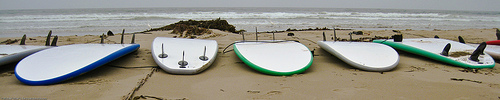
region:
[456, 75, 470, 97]
black mark is spotted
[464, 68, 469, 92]
black mark is spotted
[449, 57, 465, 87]
black mark is spotted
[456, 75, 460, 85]
black mark is spotted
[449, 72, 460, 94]
black mark is spotted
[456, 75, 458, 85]
black mark is spotted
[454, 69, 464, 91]
black mark is spotted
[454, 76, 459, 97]
black mark is spotted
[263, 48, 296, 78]
edge of a board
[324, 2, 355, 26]
edge of a shore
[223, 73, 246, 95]
part of a beach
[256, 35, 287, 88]
part of a board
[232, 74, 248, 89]
part of some sand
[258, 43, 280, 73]
surface of a board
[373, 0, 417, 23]
part of a water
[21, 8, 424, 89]
surf boards laying on ground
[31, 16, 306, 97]
paddle boards laying on ground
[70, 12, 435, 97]
foam surf boards laying on ground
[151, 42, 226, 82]
fins of surfboard sticking up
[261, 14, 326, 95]
green surfboard on ground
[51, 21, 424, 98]
white bottoms of boards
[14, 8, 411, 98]
boards upside down on groudn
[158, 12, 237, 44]
rock jetty in background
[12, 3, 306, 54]
ocean in background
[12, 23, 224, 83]
beach with sand behind boards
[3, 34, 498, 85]
a line of surf boards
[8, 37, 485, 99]
a beach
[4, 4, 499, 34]
the ocean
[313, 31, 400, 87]
a white surf board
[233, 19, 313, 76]
a green and white surf board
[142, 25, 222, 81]
a white surf board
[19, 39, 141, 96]
a white and blue surf board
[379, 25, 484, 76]
a green and white surf board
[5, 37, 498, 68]
a cable holding the surf boards together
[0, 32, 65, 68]
a white surf board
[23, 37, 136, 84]
blue and white surfboard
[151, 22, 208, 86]
white and grey surfboard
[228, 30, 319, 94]
green and white surfboard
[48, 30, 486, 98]
tan packed sand on the beach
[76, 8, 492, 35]
ocean behind the surfboards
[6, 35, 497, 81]
seven surfboards in a row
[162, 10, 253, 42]
large black rock behind surfboard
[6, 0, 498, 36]
grey overcast day at the beach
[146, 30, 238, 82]
surfboard has three fins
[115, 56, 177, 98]
line drawn in the sand